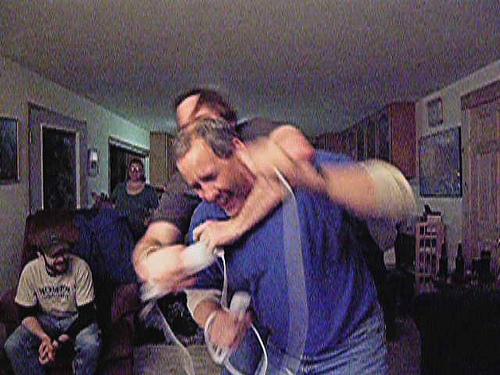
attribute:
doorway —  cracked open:
[37, 124, 86, 208]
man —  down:
[1, 226, 102, 373]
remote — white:
[230, 290, 251, 326]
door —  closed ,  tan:
[452, 78, 499, 260]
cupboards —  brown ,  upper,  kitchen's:
[305, 101, 417, 179]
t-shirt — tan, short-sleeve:
[8, 253, 100, 317]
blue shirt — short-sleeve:
[187, 147, 377, 360]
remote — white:
[198, 289, 261, 345]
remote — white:
[133, 242, 214, 279]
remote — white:
[185, 287, 280, 352]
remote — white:
[144, 236, 228, 306]